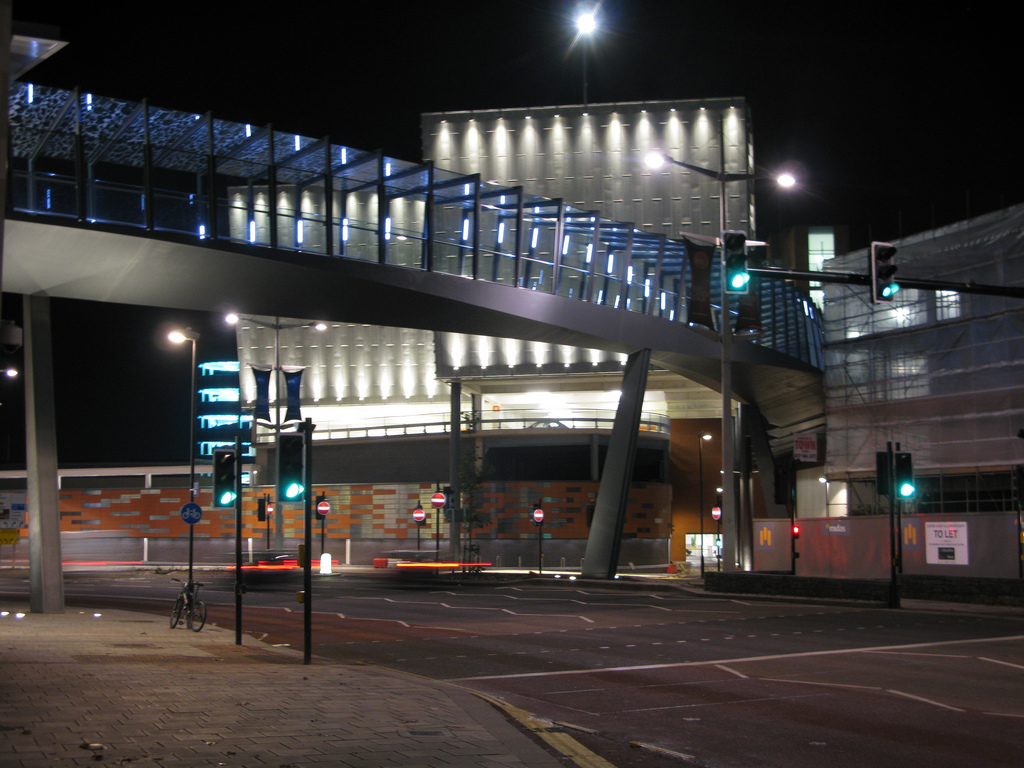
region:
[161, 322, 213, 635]
bicycle parked next to lamppost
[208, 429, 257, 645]
green traffic light on black pole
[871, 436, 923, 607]
green traffic light on black pole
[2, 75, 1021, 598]
glass walkway attached to building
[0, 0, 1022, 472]
sky is dark and black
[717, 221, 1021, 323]
green traffic lights suspended on black pole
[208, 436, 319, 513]
traffic lights on green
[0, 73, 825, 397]
walkway over the road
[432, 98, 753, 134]
multiple lights on the building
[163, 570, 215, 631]
bicycle on the street propped up by pole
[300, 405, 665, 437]
railing around second story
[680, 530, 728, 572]
doouble glass doors in front of building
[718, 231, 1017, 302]
traffic lights on a pole going across street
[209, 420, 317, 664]
two stoplights side by side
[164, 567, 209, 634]
bicycle leaned up against a pole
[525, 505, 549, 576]
do not enter sign on the road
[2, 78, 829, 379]
glass walkway above the road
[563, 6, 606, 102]
bright street light is on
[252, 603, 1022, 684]
crosswalk going across the road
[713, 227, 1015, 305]
two street lights on a horizontal pole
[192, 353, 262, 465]
parking ramp has lights on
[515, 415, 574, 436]
top of car on parking ramp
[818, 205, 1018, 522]
plastic and scaffolding on the side of a building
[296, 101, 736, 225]
a view of bulbs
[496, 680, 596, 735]
a view of road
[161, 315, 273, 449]
a view of display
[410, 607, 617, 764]
a view of lines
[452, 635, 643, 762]
lines in the road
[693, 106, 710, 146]
light on the dark building at night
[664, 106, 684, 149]
light on the dark building at night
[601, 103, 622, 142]
light on the dark building at night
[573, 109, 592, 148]
light on the dark building at night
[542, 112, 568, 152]
light on the dark building at night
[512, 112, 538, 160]
light on the dark building at night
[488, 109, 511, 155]
light on the dark building at night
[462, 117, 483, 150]
light on the dark building at night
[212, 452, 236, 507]
an electric traffic signal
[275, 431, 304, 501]
an electric traffic signal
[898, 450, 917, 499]
an electric traffic signal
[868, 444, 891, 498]
an electric traffic signal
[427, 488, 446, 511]
a do not enter sign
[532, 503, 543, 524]
a do not enter sign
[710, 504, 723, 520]
a do not enter sign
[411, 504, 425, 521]
a do not enter sign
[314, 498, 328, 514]
a do not enter sign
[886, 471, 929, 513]
green traffic light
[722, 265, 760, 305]
green traffic light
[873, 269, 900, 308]
green traffic light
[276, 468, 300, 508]
green traffic light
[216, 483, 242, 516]
green traffic light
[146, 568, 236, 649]
bike leaning on pole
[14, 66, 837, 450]
glass encased walkway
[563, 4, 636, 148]
light on roof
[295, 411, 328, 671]
black metal pole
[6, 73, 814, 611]
Glass covered walkway over road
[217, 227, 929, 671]
Set of stoplights over road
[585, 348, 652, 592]
Large grey support column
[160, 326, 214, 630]
Bicycle chained to streetlamp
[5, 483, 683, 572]
Stylish brick wall pattern along road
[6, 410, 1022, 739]
Large four lane city street